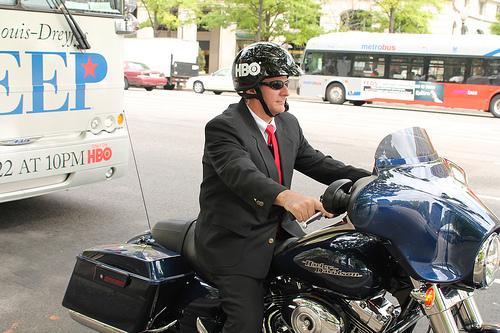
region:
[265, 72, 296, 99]
a man weaing sunglasses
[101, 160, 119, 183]
a light on the front of the bus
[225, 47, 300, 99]
a man wearing a helmet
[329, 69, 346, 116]
a tire on the bus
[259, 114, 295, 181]
a man wearing a tie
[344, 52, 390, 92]
windows on the side of the bus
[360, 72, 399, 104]
a sign on the side of the bus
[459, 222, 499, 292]
a light on the front of the motorcycle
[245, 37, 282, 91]
This is a motorcycle helmet that says "HBO"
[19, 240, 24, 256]
This asphalt has a dark black color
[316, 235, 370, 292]
This is a Harley Davidson Motorcycle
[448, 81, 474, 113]
There is a patch of red on the bus on the street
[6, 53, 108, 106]
The word "Veep" is on the bus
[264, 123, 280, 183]
This man is wearing a red tie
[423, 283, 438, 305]
There is an orange light that is here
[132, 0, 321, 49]
part of a large green tree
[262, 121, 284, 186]
a long red tie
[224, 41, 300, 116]
a black motorcycle helmet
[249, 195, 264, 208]
gold butttons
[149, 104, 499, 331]
part of a blue motorcycle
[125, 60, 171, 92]
part of a red car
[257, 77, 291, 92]
dark black sunglasses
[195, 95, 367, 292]
a man's black suit coat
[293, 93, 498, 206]
part of a roadway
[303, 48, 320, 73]
A window on a vehicle.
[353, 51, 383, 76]
A window on a vehicle.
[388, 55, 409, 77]
A window on a vehicle.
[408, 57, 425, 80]
A window on a vehicle.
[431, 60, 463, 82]
A window on a vehicle.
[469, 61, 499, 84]
A window on a vehicle.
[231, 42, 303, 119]
an HBO helmet on a man's head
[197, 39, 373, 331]
man wearing a business suit while biking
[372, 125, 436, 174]
short windshield on the motorcycle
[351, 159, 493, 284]
aerodynamic front of the cycle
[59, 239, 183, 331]
compartment for carrying items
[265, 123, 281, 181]
red tie on the cycle rider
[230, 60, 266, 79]
television logo on the helmet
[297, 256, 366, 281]
brand name on the gas tank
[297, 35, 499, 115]
a red and white bus across the street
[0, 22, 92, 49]
the name of a star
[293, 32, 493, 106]
a large bus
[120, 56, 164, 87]
a red car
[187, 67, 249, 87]
a white car on the street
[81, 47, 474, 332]
a man sitting on a motorcycle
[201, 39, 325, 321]
a man in a suit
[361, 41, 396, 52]
writing on the bus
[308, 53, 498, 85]
windows on the bus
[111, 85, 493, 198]
the street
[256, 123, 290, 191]
red tie on man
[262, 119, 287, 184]
red tie on man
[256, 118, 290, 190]
red tie on man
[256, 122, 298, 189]
red tie on man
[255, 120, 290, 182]
red tie on man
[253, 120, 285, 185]
red tie on man